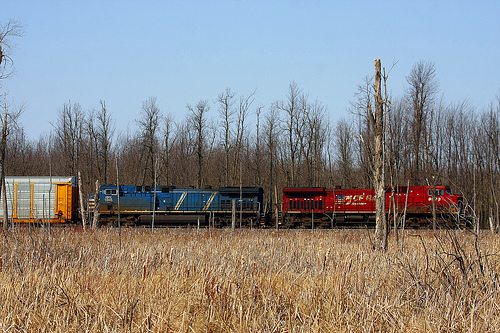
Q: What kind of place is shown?
A: It is a field.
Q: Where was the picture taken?
A: It was taken at the field.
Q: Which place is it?
A: It is a field.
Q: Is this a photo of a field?
A: Yes, it is showing a field.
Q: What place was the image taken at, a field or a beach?
A: It was taken at a field.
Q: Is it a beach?
A: No, it is a field.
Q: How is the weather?
A: It is clear.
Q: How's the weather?
A: It is clear.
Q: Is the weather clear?
A: Yes, it is clear.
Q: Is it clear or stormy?
A: It is clear.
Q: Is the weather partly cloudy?
A: No, it is clear.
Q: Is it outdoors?
A: Yes, it is outdoors.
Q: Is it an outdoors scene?
A: Yes, it is outdoors.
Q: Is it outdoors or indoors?
A: It is outdoors.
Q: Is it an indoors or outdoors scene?
A: It is outdoors.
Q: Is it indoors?
A: No, it is outdoors.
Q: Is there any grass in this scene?
A: Yes, there is grass.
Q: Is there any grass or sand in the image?
A: Yes, there is grass.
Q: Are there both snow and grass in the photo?
A: No, there is grass but no snow.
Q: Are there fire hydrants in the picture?
A: No, there are no fire hydrants.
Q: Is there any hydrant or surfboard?
A: No, there are no fire hydrants or surfboards.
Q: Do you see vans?
A: No, there are no vans.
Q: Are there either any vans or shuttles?
A: No, there are no vans or shuttles.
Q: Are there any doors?
A: Yes, there are doors.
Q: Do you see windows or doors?
A: Yes, there are doors.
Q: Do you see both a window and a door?
A: Yes, there are both a door and a window.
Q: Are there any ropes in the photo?
A: No, there are no ropes.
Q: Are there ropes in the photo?
A: No, there are no ropes.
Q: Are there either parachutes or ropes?
A: No, there are no ropes or parachutes.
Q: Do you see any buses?
A: No, there are no buses.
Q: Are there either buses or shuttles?
A: No, there are no buses or shuttles.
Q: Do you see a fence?
A: Yes, there is a fence.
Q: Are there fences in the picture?
A: Yes, there is a fence.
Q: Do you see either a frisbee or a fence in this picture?
A: Yes, there is a fence.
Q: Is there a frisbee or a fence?
A: Yes, there is a fence.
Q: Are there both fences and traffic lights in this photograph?
A: No, there is a fence but no traffic lights.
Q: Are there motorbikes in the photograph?
A: No, there are no motorbikes.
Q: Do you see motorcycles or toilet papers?
A: No, there are no motorcycles or toilet papers.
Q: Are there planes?
A: No, there are no planes.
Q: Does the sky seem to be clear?
A: Yes, the sky is clear.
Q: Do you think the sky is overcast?
A: No, the sky is clear.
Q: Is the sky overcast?
A: No, the sky is clear.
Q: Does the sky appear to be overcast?
A: No, the sky is clear.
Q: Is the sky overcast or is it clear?
A: The sky is clear.